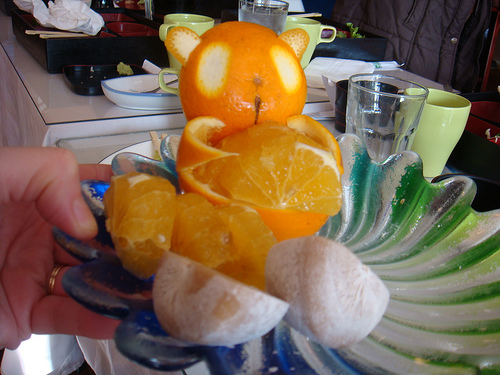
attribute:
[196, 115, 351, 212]
orange — peeled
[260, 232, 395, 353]
orange — peeled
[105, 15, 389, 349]
fruit — bear shaped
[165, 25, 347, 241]
bear — orange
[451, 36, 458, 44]
jacket button — silver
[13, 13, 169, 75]
tray — black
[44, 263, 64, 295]
band — gold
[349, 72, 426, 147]
cup — glass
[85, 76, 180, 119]
dish — white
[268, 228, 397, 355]
orange — sliced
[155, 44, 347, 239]
oranes — bear shaped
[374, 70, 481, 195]
cup — yellow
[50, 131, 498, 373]
plate — blue and green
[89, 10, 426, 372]
oranges — bear shaped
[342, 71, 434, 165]
glass — clear